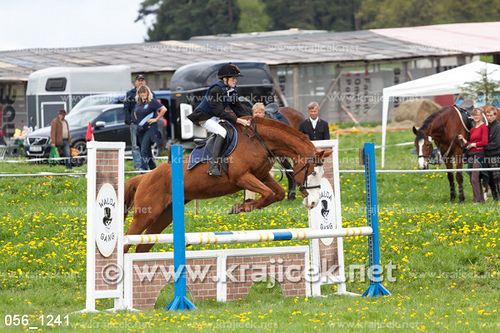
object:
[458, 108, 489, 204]
woman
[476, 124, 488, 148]
sleeve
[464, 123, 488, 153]
shirt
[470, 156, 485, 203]
pants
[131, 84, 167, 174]
blonde woman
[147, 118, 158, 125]
hand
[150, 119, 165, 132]
hip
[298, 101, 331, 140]
man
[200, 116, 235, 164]
jeans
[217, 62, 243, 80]
hat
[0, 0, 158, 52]
sky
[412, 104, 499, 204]
horse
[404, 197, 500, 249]
flowers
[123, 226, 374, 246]
bar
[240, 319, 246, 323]
flower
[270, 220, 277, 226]
flower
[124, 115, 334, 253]
brown horse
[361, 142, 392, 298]
blue pole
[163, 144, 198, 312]
blue pole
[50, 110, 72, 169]
man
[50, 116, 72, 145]
coat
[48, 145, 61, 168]
sack